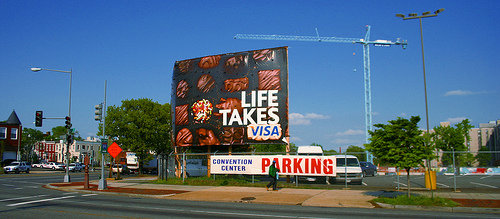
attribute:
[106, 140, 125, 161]
street sign — orange, diamond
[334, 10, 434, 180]
light — red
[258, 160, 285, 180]
jacket — green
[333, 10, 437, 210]
light — white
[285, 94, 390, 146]
clouds — white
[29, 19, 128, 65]
sky — blue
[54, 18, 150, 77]
sky — blue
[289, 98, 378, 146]
clouds — white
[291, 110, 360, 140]
clouds — white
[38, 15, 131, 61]
sky — blue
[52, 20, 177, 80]
sky — blue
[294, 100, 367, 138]
clouds — white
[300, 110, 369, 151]
clouds — white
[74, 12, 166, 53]
sky — blue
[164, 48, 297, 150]
billboard — colorful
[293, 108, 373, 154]
clouds — white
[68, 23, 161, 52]
sky — blue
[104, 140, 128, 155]
sign — red, street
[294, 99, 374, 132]
clouds — white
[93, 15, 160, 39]
sky — blue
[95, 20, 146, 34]
sky — blue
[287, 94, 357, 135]
clouds — white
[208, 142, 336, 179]
sign — white, red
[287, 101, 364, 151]
clouds — white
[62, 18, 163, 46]
sky — blue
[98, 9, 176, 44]
sky — blue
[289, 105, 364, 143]
clouds — white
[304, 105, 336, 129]
clouds — white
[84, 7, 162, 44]
sky — blue